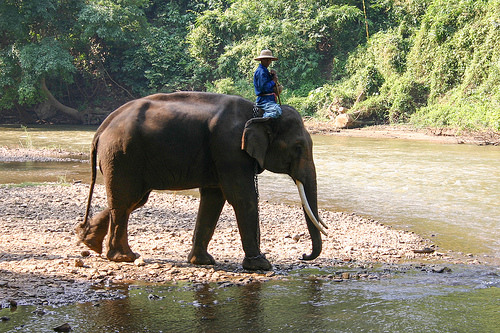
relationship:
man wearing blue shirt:
[253, 49, 283, 118] [253, 63, 277, 105]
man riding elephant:
[250, 48, 284, 119] [74, 90, 330, 270]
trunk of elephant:
[292, 171, 324, 261] [74, 90, 330, 270]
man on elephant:
[253, 49, 283, 118] [74, 90, 330, 270]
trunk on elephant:
[292, 171, 322, 260] [74, 90, 330, 270]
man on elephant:
[253, 49, 283, 118] [54, 94, 366, 278]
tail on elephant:
[80, 142, 97, 228] [74, 90, 330, 270]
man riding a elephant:
[253, 49, 283, 118] [74, 90, 330, 270]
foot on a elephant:
[70, 207, 108, 256] [76, 90, 327, 270]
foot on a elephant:
[103, 239, 133, 266] [76, 90, 327, 270]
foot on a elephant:
[183, 248, 221, 271] [76, 90, 327, 270]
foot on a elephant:
[234, 248, 275, 273] [76, 90, 327, 270]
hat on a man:
[254, 50, 279, 61] [252, 56, 282, 104]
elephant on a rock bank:
[74, 90, 330, 270] [0, 234, 440, 299]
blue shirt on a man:
[252, 64, 279, 100] [253, 49, 283, 118]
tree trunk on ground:
[327, 107, 368, 135] [356, 117, 441, 141]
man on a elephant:
[253, 49, 283, 118] [74, 90, 330, 270]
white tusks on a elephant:
[294, 176, 331, 243] [74, 90, 330, 270]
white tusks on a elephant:
[318, 210, 334, 231] [74, 90, 330, 270]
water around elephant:
[1, 125, 498, 329] [74, 90, 330, 270]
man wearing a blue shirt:
[253, 49, 283, 118] [252, 64, 279, 104]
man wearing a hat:
[253, 49, 283, 118] [254, 45, 276, 62]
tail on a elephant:
[81, 135, 100, 230] [74, 90, 330, 270]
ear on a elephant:
[242, 111, 274, 163] [83, 84, 324, 265]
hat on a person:
[254, 48, 279, 63] [245, 44, 292, 129]